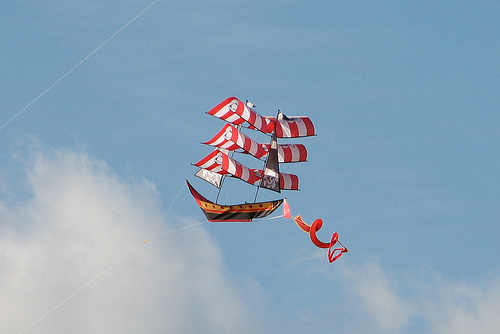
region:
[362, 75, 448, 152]
blue sky in the photo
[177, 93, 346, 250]
kite in the air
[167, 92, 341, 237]
red and white kite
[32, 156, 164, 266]
cloud in the sky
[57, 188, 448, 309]
many clouds in the sky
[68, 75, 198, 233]
white and blue sky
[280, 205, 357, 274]
tail of the kite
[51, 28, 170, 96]
string in the air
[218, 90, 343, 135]
top of the kite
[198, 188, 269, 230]
bottom of the kite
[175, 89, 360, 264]
Boat kite flying in sky.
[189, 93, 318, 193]
Red and white sails on kite.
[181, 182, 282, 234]
Red, yellow, and black ship.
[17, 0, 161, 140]
White chem trail in sky.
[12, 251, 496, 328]
White clouds in blue sky.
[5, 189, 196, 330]
White strings attached to kite.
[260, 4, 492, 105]
Clear blue part of sky.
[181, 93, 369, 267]
Large ship kite in air.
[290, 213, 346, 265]
Red tail of kite.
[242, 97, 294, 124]
Black and white flags on kite.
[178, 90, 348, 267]
a kite in the sky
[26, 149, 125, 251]
the cloud is white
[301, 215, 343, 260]
a red ribbon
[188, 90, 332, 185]
kite is red and white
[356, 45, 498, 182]
the sky is clear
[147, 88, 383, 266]
the kite is in the sky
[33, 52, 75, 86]
a line in the sky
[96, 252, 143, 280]
a white string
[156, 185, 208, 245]
two strings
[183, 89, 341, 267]
the kite is in the air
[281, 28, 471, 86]
Clear blue cloudless sky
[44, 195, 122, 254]
White patch of cloud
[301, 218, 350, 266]
Red spiral shaped material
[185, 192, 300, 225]
Boat shaped kite piece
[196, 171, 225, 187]
White patch of kite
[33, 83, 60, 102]
Long narrow white string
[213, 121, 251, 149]
Red and white material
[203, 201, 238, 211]
Yellow material kite piece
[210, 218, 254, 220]
Thin narrow red base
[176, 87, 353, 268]
A big storied kite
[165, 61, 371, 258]
this is a kite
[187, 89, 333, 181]
the sails of the kite are red and white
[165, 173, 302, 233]
the kite is shaped like a boat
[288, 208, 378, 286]
the tail of the kite is red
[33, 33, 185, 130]
this is the string holding the kite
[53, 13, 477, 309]
the kite is kept up with wind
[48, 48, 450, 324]
the weather is partly cloudy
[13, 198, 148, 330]
the clouds are fluffy and white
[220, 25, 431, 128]
the sky is a very light blue